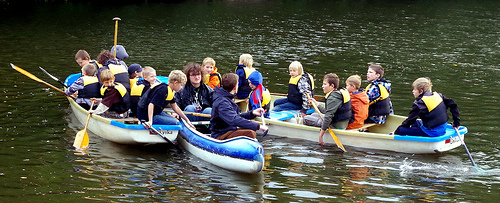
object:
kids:
[301, 71, 356, 146]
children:
[135, 69, 200, 130]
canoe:
[60, 73, 185, 146]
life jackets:
[76, 82, 131, 107]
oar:
[69, 129, 91, 152]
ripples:
[0, 1, 499, 203]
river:
[0, 0, 499, 203]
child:
[342, 74, 370, 129]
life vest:
[344, 91, 370, 128]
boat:
[217, 91, 469, 153]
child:
[76, 70, 132, 118]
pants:
[214, 127, 256, 140]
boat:
[146, 76, 266, 174]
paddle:
[73, 97, 97, 154]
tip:
[71, 144, 87, 150]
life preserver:
[417, 91, 450, 128]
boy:
[390, 77, 461, 137]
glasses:
[188, 71, 205, 77]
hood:
[349, 89, 371, 103]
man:
[207, 71, 270, 141]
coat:
[205, 87, 260, 138]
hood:
[204, 89, 226, 104]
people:
[358, 65, 396, 127]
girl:
[175, 62, 213, 121]